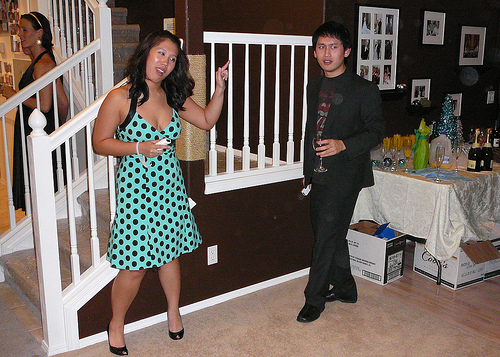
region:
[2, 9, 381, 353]
three people in a basement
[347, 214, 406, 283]
a white and black cardboard box on the floor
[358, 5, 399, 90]
framed pictures on the wall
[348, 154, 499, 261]
a white tablecloth on a table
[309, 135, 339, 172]
young man holding a glass of wine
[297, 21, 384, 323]
young man wearing a black suit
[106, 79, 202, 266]
young woman wearing a blue dress with black polka dots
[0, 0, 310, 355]
white stairs leading to the basement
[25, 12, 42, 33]
woman wearing a golden headband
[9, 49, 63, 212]
woman wearing a black dress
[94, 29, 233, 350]
a girl wearing dress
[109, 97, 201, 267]
a teal dress with black dots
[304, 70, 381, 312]
a black suit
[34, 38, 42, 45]
a sparkling earring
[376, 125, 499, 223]
table top of refreshments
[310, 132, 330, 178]
a clear wine glass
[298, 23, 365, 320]
a guy holding a glass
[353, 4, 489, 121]
pictures on the wall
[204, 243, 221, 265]
a white electrical socket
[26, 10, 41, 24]
a gold headband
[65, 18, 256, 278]
woman wearing blue dress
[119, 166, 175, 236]
black dots on dress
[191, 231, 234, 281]
outlet on the wall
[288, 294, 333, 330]
shoe on the foot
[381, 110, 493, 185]
items on the table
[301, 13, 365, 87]
head of a boy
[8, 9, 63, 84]
girl in the background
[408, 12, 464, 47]
picture on the wall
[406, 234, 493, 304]
box under the table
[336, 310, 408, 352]
floor under the guy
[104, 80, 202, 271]
A teal dress with black polka dots.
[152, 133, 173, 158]
A white wii controller.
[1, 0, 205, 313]
Carpeted stairs.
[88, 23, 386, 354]
Two people playing the wii.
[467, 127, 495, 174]
Bottles of champaign.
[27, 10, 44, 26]
A headband.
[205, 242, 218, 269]
A white panel on the wall.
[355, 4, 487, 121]
Pictures hanging on the wall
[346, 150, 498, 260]
A white tablecloth.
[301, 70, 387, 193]
A black blazer.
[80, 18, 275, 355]
girl in a polka dot dress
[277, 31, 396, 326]
man in a suit with wine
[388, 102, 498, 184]
decorations on a table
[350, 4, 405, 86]
photo on the wall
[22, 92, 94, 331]
wooden railing on steps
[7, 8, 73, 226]
woman with a gold headband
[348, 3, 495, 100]
pictures hanging on a wall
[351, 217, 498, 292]
wine boxes under table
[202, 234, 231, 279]
electrical outlet on wall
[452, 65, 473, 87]
picture of a planet on the wall